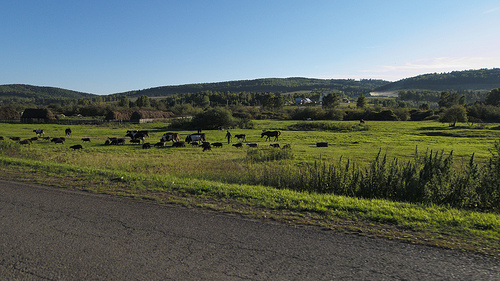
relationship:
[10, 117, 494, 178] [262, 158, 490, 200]
pasture has weeds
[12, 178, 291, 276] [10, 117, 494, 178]
road next to pasture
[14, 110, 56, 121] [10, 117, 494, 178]
building next to pasture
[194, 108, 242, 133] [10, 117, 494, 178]
tree in pasture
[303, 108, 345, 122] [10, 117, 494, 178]
bushes in pasture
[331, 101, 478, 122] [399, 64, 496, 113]
trees near hillside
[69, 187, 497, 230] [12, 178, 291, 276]
grass next to road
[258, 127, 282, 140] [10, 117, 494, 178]
horse in field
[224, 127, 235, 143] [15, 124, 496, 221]
man in field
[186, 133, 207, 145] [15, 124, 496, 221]
cow in field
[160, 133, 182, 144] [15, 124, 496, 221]
cow in field